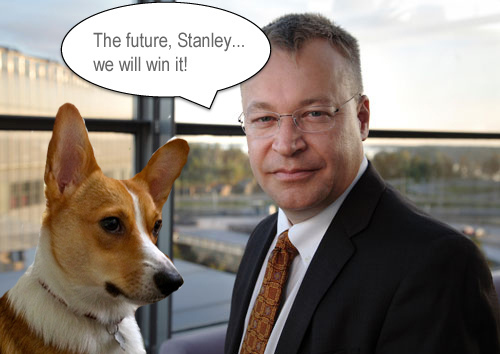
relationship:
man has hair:
[224, 12, 499, 352] [258, 9, 365, 100]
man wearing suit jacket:
[224, 12, 499, 352] [351, 228, 446, 338]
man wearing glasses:
[224, 12, 499, 352] [237, 90, 361, 139]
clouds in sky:
[414, 17, 481, 118] [0, 0, 500, 148]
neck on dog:
[30, 262, 124, 337] [3, 99, 197, 352]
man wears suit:
[224, 12, 499, 352] [200, 153, 499, 347]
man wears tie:
[224, 12, 499, 352] [248, 218, 298, 348]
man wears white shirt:
[224, 12, 499, 352] [239, 155, 373, 352]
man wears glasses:
[224, 12, 499, 352] [236, 94, 362, 140]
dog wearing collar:
[3, 99, 197, 352] [24, 255, 129, 347]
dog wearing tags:
[3, 99, 197, 352] [110, 324, 132, 349]